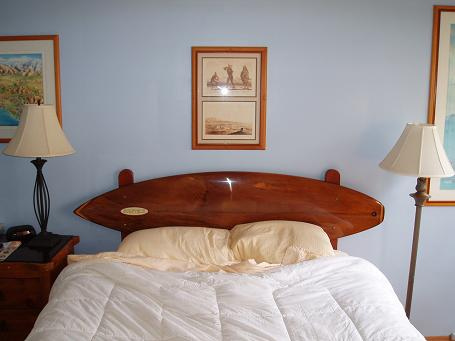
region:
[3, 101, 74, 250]
a very prety bedside lamp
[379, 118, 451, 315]
a very prety bedside lamp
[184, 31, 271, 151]
a picture on the wall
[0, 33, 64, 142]
a picture on the wall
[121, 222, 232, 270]
the pillow is cream in color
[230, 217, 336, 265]
the pillow is cream in color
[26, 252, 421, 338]
a white bed-cover on the bed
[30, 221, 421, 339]
this is a well spread bed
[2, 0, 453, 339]
the bedroom wall is painted blue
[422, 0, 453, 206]
a picture on the wall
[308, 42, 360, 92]
part of a wall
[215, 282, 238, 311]
part of a sheet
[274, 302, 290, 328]
part of a line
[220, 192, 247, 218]
part of a wood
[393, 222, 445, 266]
part of a post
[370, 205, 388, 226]
edge of a wood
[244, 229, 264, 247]
part of a pillow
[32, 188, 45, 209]
part of a stand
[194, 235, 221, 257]
part of a cloth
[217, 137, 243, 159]
part of a frame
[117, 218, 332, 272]
two peach pillows lying side by side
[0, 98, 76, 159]
ivory lamp shade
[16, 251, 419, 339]
puffy white bedspread neatly laying on the bed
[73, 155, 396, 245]
surfboard shaped wooden headboard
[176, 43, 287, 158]
artwork in a rectangular frame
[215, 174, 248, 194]
light reflecting off the headboard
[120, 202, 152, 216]
small gold sticker on the headboard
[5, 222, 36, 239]
black alarm clock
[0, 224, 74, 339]
brown wooden night stand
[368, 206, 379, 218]
black circle on the headboard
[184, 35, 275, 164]
two pictures in one frame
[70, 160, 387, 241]
a headboard the shape of a surfboard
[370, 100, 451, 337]
a floorlamp on the right of the bed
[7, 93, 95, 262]
a black lamp on the nightstand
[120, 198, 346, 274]
two cream colored pillows on the bed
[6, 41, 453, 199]
three pictures on wall in bedroom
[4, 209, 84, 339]
a wood nightstand on left of the bed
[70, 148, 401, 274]
a wood headboard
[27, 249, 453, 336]
a white comforter on the bed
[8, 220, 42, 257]
a black alarm clock on the nightstand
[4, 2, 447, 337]
a bedroom setting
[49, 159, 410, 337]
a bed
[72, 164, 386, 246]
a headboard in the shape of a surfboard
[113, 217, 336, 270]
pillows on a bed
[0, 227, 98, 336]
a bedside table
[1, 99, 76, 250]
a table lamp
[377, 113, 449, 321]
a floor lamp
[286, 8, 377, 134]
the wall is blue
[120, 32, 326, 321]
framed artwork above bed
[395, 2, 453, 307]
large framed artwork to the right of floor lamp